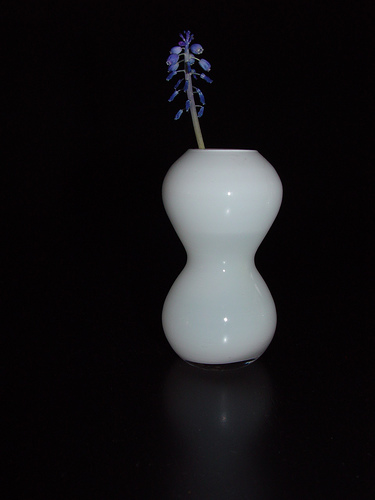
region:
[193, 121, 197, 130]
The stem of a flower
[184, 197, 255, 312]
Vase with shape of figure eight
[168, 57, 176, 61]
A blue flower bud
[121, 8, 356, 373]
white vase with a purple flower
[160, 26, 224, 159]
one purple flower in white vase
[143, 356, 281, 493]
reflection of white vase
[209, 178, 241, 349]
light shining on white vase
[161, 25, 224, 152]
purple flower with brown stem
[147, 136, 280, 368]
curvy white vase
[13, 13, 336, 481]
black background behind and under vase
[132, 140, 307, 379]
one white vase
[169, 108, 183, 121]
small purple flowers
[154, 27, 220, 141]
stem with blue flowers in the vase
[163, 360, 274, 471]
shadow of the vase on the ground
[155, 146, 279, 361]
vase is white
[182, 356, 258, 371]
clear glass at the very bottom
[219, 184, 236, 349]
reflection of lights on the vase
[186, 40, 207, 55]
little flower is open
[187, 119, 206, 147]
stem is thick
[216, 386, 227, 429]
reflection of light in the shadow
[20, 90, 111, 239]
background is completely black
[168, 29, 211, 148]
a blue flower in the vase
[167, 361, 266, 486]
the vase reflection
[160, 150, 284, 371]
a white decorative vase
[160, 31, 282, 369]
a white vase with a flower in it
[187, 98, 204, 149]
a single stem in the vase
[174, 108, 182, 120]
a blue flower pedal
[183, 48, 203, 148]
the flower stem white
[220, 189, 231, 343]
light reflections on the vase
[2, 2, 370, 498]
the background is black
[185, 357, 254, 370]
glass bottom on the vase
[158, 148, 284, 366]
hourglass shaped white vase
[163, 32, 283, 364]
white ceramic vase with one flower stalk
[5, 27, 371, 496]
one single white vase on black table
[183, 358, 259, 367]
clear base of white flower vase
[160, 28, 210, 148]
purple flower stalk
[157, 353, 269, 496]
reflection of white vase on shiny black table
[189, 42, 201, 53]
individual purple flower bloom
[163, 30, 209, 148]
flower stalk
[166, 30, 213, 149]
flower stalk with opened and unopened flowers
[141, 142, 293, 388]
a white vase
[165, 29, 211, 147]
a blue flower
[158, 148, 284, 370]
a white colored vase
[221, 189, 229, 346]
lights reflecting on the vase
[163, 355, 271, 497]
reflection of vase on the table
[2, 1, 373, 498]
shiny black table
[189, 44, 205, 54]
an blue and white colored flower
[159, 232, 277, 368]
a translucent part of the vase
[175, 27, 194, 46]
closed flower buds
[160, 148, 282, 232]
an opaque section of the vase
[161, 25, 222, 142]
Purple flower.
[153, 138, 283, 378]
Hourglass shaped vase.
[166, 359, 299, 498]
Reflection of vase on a black surface.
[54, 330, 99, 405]
Black background.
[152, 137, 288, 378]
White glass vase.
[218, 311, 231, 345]
Light reflecting off the vase.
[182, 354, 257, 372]
Clear bottom of the base.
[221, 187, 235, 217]
Light reflecting off the top of the vase.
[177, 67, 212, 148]
A long thick stem.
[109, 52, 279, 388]
this is a vase